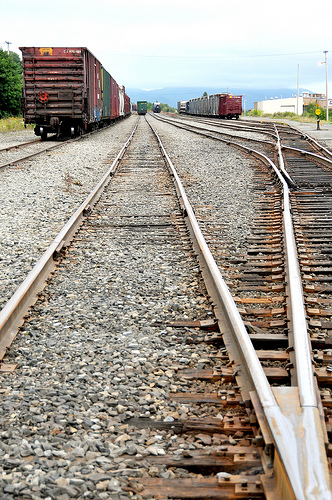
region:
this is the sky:
[148, 35, 232, 81]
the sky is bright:
[134, 51, 167, 74]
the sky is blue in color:
[183, 47, 224, 76]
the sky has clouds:
[229, 58, 252, 72]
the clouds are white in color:
[212, 63, 235, 74]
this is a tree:
[1, 50, 20, 114]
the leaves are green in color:
[0, 60, 15, 86]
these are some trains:
[10, 40, 252, 132]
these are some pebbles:
[41, 395, 118, 462]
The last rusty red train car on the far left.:
[18, 46, 102, 136]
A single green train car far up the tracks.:
[136, 101, 149, 117]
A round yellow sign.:
[313, 108, 321, 116]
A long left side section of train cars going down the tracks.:
[20, 46, 133, 136]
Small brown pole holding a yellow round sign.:
[315, 105, 320, 130]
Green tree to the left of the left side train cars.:
[0, 50, 24, 114]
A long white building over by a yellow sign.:
[253, 95, 330, 114]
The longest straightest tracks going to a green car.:
[0, 114, 298, 499]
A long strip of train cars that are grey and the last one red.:
[185, 94, 243, 120]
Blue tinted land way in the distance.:
[124, 86, 316, 114]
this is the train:
[18, 52, 118, 117]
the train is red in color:
[22, 47, 101, 118]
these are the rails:
[246, 122, 304, 164]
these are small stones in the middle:
[51, 291, 142, 383]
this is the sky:
[152, 6, 232, 58]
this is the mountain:
[165, 85, 186, 96]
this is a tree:
[0, 57, 17, 92]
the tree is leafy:
[0, 55, 21, 90]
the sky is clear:
[148, 31, 208, 60]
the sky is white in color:
[160, 16, 232, 59]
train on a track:
[16, 34, 133, 126]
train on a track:
[177, 88, 245, 120]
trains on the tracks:
[137, 98, 165, 122]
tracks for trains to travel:
[254, 118, 330, 212]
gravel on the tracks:
[192, 146, 232, 182]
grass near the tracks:
[0, 116, 23, 131]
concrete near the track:
[304, 123, 327, 136]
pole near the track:
[285, 62, 309, 118]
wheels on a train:
[23, 123, 82, 139]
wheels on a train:
[221, 111, 244, 120]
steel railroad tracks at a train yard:
[273, 133, 328, 499]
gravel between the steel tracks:
[86, 175, 167, 499]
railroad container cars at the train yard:
[16, 45, 130, 135]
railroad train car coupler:
[48, 114, 62, 130]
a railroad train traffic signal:
[314, 100, 324, 130]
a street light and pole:
[318, 47, 331, 121]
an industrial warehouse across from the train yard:
[252, 94, 304, 116]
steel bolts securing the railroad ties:
[217, 470, 263, 495]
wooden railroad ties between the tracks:
[295, 188, 331, 253]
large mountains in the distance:
[127, 82, 189, 100]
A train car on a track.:
[207, 93, 222, 114]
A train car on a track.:
[200, 96, 212, 114]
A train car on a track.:
[195, 97, 207, 114]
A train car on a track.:
[186, 100, 200, 114]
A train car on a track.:
[178, 101, 187, 112]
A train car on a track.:
[138, 101, 146, 112]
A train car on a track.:
[20, 39, 101, 135]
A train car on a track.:
[99, 68, 111, 115]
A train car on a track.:
[109, 80, 120, 116]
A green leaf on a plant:
[2, 70, 5, 71]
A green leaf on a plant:
[15, 81, 18, 82]